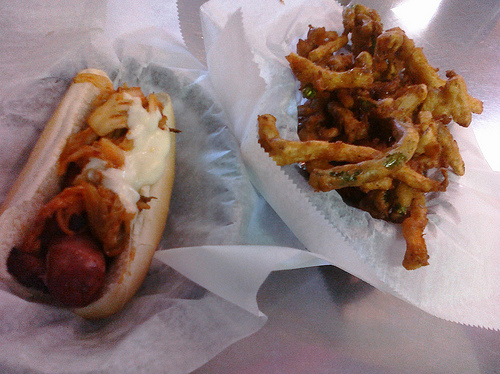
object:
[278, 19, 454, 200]
food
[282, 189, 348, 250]
paper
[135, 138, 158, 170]
sauce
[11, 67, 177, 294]
hot dog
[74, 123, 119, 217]
toppings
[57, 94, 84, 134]
bun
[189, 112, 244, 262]
tray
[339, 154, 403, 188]
green food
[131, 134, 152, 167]
cheese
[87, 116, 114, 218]
condiments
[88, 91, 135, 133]
food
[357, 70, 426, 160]
fried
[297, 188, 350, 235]
dish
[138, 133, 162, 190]
mayonnaise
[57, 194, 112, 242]
onions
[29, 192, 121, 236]
red sauce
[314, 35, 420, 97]
bunch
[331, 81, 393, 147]
vegetable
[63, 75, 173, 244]
sandwich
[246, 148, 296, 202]
basket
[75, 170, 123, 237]
fixings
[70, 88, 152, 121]
eat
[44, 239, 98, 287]
cooked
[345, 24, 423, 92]
asparagus